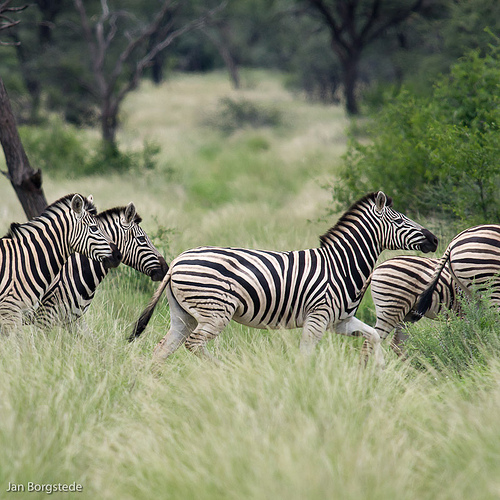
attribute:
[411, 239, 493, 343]
tail — white, black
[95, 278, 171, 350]
tail — black, white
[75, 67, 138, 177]
tree — blurry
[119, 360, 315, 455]
grass — brown, tall, green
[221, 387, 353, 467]
grass — long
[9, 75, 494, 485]
grass — tall, brown, green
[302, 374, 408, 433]
grass — green, tall, brown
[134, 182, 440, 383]
zebra — black, white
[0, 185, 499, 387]
zebras — pack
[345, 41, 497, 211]
tree — green, short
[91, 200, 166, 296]
head — white, black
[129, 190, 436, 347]
zebra — black, white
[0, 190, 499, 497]
grass — high grass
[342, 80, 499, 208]
shrub — green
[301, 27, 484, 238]
tree — short, green